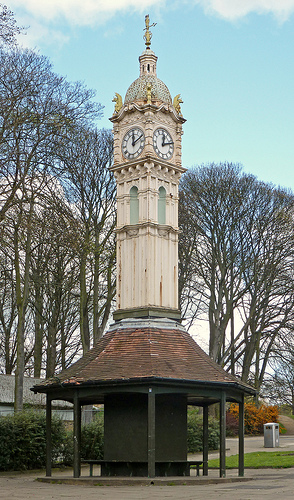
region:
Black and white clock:
[118, 127, 146, 163]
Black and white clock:
[151, 125, 177, 162]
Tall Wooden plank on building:
[142, 392, 163, 477]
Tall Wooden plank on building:
[217, 394, 230, 480]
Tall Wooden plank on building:
[235, 399, 248, 478]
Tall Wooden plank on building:
[63, 404, 81, 476]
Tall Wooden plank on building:
[39, 398, 59, 479]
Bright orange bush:
[243, 403, 292, 437]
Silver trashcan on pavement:
[257, 413, 284, 455]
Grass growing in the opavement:
[87, 480, 124, 489]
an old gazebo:
[28, 318, 258, 491]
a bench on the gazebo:
[82, 456, 146, 475]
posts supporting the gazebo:
[43, 394, 245, 479]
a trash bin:
[263, 421, 280, 447]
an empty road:
[281, 410, 293, 436]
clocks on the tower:
[122, 124, 174, 160]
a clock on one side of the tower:
[121, 126, 145, 158]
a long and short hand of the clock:
[130, 127, 143, 145]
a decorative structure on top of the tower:
[108, 82, 188, 124]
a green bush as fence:
[1, 413, 38, 467]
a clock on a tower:
[90, 8, 192, 322]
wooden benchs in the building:
[88, 449, 207, 474]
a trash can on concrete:
[257, 419, 283, 454]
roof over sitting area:
[32, 323, 266, 397]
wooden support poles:
[144, 387, 178, 474]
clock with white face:
[122, 122, 148, 163]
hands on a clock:
[128, 129, 145, 151]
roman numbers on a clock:
[135, 138, 150, 156]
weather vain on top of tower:
[139, 13, 163, 50]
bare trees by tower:
[27, 209, 123, 358]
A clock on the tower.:
[114, 121, 164, 167]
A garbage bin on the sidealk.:
[255, 411, 282, 456]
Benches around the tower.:
[69, 442, 210, 469]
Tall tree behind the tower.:
[24, 146, 112, 352]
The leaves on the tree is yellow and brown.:
[246, 397, 280, 423]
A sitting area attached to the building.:
[71, 444, 192, 478]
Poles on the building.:
[66, 386, 159, 475]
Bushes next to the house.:
[2, 408, 99, 468]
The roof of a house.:
[8, 373, 65, 410]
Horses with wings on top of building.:
[106, 91, 126, 119]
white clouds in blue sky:
[27, 4, 69, 37]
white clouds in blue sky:
[70, 14, 107, 47]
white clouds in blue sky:
[78, 51, 100, 70]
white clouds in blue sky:
[90, 6, 122, 43]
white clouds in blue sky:
[168, 19, 210, 55]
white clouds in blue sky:
[177, 50, 211, 88]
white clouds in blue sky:
[226, 14, 278, 57]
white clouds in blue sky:
[212, 80, 263, 147]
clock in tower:
[120, 123, 139, 153]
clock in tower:
[155, 120, 179, 175]